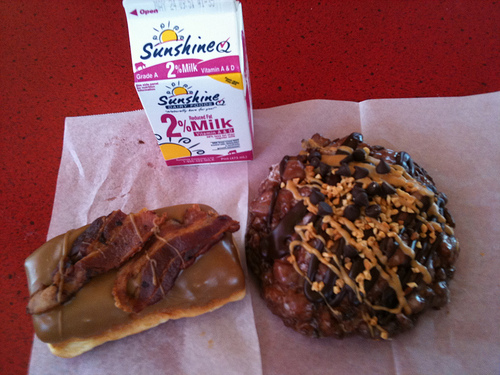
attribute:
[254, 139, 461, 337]
donut — round, messy, rectangler, chocolate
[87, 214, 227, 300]
bacon — cooked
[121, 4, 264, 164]
milk — sunshine brand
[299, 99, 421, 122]
paper — white, wrinkled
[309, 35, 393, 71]
table — red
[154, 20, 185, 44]
sunshine symbol — little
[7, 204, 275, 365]
food — fried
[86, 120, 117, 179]
napkin — creased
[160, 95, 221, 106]
letters — fuchsia, fushia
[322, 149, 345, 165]
frosting — maple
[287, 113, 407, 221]
pastry — oblong, round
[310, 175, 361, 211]
topping — brown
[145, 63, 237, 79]
carton — pink, white, blue, yellow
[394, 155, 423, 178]
icing — carmel